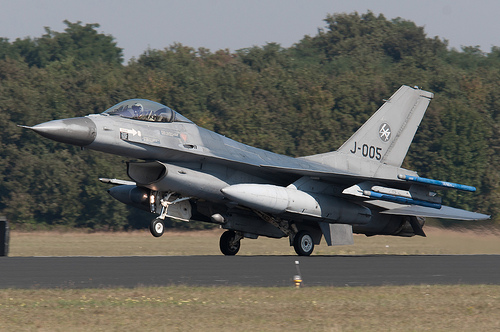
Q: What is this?
A: An airplane.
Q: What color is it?
A: Gray.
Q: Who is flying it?
A: The pilot.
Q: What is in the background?
A: Trees.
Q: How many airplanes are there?
A: One.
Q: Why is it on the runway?
A: It is taking off.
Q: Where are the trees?
A: Behind the plane.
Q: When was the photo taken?
A: Daytime.